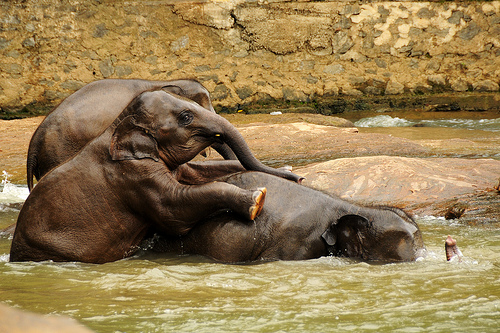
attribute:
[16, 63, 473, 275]
elephants — grey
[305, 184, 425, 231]
hair — tufty, black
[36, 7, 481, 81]
rocks — rough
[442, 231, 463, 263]
elephant — submerged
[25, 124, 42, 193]
tail — gray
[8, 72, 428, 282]
elephants — gray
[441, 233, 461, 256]
elephant nose — gray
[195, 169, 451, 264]
elephant — gray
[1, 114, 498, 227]
flat rocks — big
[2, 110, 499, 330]
water — murky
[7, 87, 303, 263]
elephants — gray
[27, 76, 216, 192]
elephants — gray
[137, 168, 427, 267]
elephants — gray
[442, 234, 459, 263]
elephants — gray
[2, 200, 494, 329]
water — green, murky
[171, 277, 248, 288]
water — murky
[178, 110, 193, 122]
eye — black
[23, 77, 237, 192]
elephant — gray, swimming, wet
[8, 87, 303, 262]
elephant — swimming, wet, playing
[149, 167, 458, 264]
elephant — swimming, wet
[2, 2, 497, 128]
rocks — wet, multicolored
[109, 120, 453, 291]
elephants — grey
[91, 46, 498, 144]
wall — cement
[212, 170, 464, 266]
elephant — playing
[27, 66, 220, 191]
elephant — playing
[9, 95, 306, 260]
three elephants — gray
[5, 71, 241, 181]
three elephants — gray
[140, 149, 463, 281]
three elephants — gray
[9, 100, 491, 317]
river — flowing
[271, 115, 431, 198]
rock — high